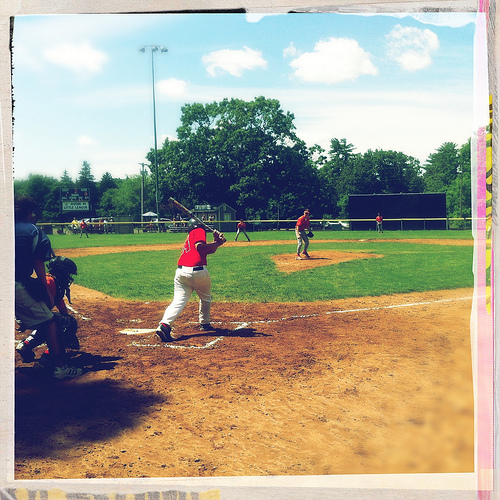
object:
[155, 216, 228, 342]
man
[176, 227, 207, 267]
shirt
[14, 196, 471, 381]
game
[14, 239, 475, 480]
dirt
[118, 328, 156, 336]
plate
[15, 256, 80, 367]
catcher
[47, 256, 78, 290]
mask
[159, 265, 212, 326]
pants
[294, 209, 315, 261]
pitcher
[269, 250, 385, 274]
mound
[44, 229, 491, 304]
grass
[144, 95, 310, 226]
tree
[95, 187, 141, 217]
tree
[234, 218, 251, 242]
player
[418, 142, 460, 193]
tree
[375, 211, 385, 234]
player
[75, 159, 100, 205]
tree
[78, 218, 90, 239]
player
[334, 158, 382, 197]
tree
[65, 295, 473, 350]
path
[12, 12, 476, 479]
outside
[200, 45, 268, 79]
cloud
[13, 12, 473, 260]
distance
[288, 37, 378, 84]
cloud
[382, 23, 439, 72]
cloud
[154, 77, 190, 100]
cloud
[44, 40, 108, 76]
cloud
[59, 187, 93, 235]
sign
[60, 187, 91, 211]
information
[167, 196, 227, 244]
bat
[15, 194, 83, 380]
umpire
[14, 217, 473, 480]
field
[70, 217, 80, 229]
person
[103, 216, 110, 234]
person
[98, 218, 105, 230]
person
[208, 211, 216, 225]
person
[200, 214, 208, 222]
person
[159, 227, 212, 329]
uniform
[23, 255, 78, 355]
uniform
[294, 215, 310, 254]
uniform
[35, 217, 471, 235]
fence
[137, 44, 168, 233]
pole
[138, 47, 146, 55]
light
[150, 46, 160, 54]
light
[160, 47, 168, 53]
light